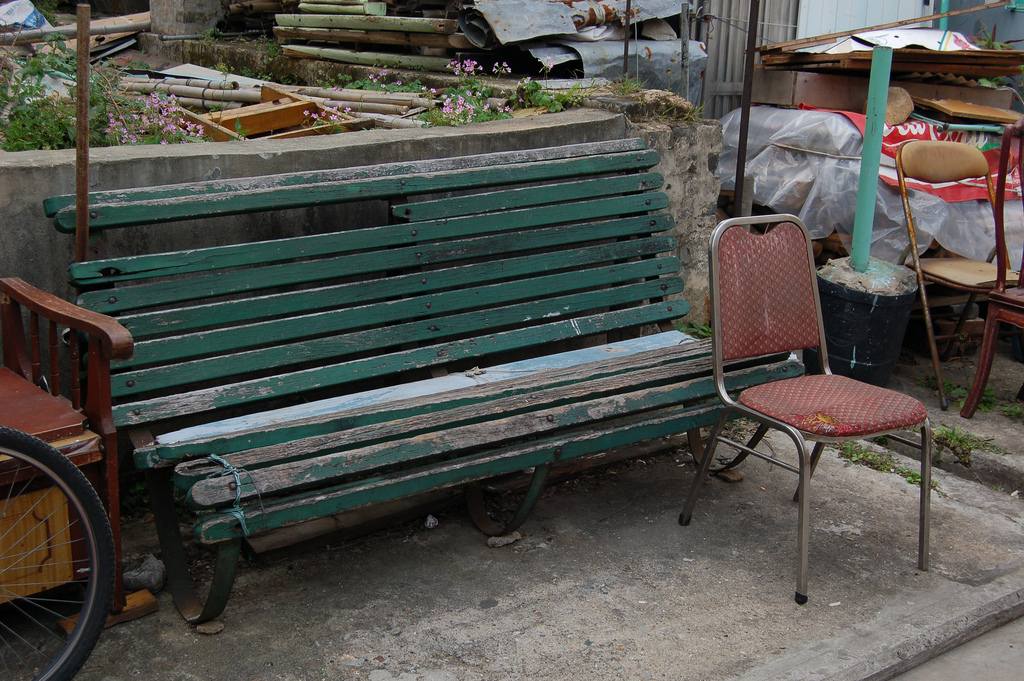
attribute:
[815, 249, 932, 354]
bucket — black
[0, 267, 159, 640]
chair — wooden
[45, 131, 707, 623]
bench — green, wooden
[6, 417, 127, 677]
tire — bike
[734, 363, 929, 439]
seat — fabric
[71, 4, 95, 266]
pole — wood